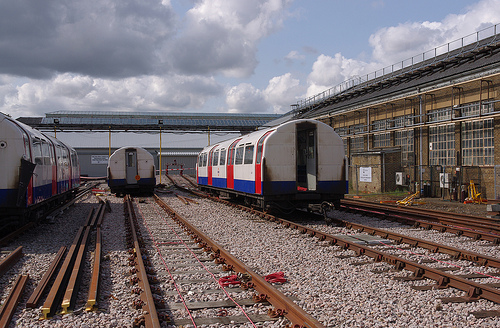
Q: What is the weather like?
A: It is cloudy.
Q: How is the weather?
A: It is cloudy.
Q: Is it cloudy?
A: Yes, it is cloudy.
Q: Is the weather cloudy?
A: Yes, it is cloudy.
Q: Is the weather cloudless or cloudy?
A: It is cloudy.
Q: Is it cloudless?
A: No, it is cloudy.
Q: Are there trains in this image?
A: Yes, there is a train.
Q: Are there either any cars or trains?
A: Yes, there is a train.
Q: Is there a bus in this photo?
A: No, there are no buses.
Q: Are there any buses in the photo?
A: No, there are no buses.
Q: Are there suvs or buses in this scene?
A: No, there are no buses or suvs.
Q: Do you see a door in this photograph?
A: Yes, there is a door.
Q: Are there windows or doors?
A: Yes, there is a door.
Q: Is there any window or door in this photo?
A: Yes, there is a door.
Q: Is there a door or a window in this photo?
A: Yes, there is a door.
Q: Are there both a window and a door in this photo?
A: Yes, there are both a door and a window.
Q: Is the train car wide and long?
A: Yes, the train car is wide and long.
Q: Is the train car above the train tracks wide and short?
A: No, the train car is wide but long.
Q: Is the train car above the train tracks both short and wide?
A: No, the train car is wide but long.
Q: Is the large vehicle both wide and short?
A: No, the train car is wide but long.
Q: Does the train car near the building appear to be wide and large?
A: Yes, the train car is wide and large.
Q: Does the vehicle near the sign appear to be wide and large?
A: Yes, the train car is wide and large.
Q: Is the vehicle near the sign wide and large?
A: Yes, the train car is wide and large.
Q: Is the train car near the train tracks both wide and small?
A: No, the train car is wide but large.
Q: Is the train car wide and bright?
A: Yes, the train car is wide and bright.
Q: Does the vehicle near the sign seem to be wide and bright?
A: Yes, the train car is wide and bright.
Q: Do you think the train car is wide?
A: Yes, the train car is wide.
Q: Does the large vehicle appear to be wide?
A: Yes, the train car is wide.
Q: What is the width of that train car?
A: The train car is wide.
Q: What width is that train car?
A: The train car is wide.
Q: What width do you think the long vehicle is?
A: The train car is wide.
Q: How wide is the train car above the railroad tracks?
A: The train car is wide.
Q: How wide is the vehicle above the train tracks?
A: The train car is wide.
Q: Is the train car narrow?
A: No, the train car is wide.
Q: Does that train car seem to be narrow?
A: No, the train car is wide.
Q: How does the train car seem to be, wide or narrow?
A: The train car is wide.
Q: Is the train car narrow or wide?
A: The train car is wide.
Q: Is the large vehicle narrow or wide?
A: The train car is wide.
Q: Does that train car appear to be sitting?
A: Yes, the train car is sitting.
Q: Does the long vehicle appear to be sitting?
A: Yes, the train car is sitting.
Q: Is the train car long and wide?
A: Yes, the train car is long and wide.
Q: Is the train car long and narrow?
A: No, the train car is long but wide.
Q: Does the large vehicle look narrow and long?
A: No, the train car is long but wide.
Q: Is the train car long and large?
A: Yes, the train car is long and large.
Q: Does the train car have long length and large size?
A: Yes, the train car is long and large.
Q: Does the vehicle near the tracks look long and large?
A: Yes, the train car is long and large.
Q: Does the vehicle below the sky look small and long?
A: No, the train car is long but large.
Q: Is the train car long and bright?
A: Yes, the train car is long and bright.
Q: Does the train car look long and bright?
A: Yes, the train car is long and bright.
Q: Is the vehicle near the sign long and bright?
A: Yes, the train car is long and bright.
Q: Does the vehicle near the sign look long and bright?
A: Yes, the train car is long and bright.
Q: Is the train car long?
A: Yes, the train car is long.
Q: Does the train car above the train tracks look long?
A: Yes, the train car is long.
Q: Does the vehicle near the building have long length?
A: Yes, the train car is long.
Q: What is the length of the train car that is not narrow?
A: The train car is long.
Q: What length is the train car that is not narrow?
A: The train car is long.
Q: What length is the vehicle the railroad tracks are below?
A: The train car is long.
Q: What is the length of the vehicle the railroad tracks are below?
A: The train car is long.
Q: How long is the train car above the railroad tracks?
A: The train car is long.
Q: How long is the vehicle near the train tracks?
A: The train car is long.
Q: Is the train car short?
A: No, the train car is long.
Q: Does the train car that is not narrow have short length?
A: No, the train car is long.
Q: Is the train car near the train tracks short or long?
A: The train car is long.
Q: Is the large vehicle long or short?
A: The train car is long.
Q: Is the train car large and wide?
A: Yes, the train car is large and wide.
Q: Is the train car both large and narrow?
A: No, the train car is large but wide.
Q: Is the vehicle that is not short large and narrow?
A: No, the train car is large but wide.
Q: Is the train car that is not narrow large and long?
A: Yes, the train car is large and long.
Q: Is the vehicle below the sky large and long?
A: Yes, the train car is large and long.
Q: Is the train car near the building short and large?
A: No, the train car is large but long.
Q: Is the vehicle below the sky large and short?
A: No, the train car is large but long.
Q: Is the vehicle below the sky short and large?
A: No, the train car is large but long.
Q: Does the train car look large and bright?
A: Yes, the train car is large and bright.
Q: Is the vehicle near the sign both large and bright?
A: Yes, the train car is large and bright.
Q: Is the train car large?
A: Yes, the train car is large.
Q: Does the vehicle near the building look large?
A: Yes, the train car is large.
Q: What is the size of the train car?
A: The train car is large.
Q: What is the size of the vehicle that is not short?
A: The train car is large.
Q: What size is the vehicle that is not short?
A: The train car is large.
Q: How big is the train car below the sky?
A: The train car is large.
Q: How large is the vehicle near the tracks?
A: The train car is large.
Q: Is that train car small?
A: No, the train car is large.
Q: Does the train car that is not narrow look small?
A: No, the train car is large.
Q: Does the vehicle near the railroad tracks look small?
A: No, the train car is large.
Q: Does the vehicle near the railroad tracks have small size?
A: No, the train car is large.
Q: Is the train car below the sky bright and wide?
A: Yes, the train car is bright and wide.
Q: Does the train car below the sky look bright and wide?
A: Yes, the train car is bright and wide.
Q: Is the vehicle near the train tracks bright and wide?
A: Yes, the train car is bright and wide.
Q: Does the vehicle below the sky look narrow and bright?
A: No, the train car is bright but wide.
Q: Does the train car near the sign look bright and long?
A: Yes, the train car is bright and long.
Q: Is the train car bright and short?
A: No, the train car is bright but long.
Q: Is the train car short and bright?
A: No, the train car is bright but long.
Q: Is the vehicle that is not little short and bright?
A: No, the train car is bright but long.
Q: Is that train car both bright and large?
A: Yes, the train car is bright and large.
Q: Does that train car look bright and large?
A: Yes, the train car is bright and large.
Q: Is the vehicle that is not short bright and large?
A: Yes, the train car is bright and large.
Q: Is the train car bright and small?
A: No, the train car is bright but large.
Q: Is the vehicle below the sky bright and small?
A: No, the train car is bright but large.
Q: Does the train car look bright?
A: Yes, the train car is bright.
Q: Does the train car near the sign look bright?
A: Yes, the train car is bright.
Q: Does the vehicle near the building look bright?
A: Yes, the train car is bright.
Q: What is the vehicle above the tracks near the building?
A: The vehicle is a train car.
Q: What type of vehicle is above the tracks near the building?
A: The vehicle is a train car.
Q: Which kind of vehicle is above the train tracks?
A: The vehicle is a train car.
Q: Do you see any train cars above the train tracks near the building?
A: Yes, there is a train car above the train tracks.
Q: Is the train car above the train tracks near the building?
A: Yes, the train car is above the train tracks.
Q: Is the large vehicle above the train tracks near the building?
A: Yes, the train car is above the train tracks.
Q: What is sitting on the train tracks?
A: The train car is sitting on the train tracks.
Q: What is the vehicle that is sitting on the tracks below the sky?
A: The vehicle is a train car.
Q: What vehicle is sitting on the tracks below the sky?
A: The vehicle is a train car.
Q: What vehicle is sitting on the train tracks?
A: The vehicle is a train car.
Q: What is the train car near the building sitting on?
A: The train car is sitting on the train tracks.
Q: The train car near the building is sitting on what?
A: The train car is sitting on the train tracks.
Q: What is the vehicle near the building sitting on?
A: The train car is sitting on the train tracks.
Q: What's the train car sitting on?
A: The train car is sitting on the train tracks.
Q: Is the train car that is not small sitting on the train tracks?
A: Yes, the train car is sitting on the train tracks.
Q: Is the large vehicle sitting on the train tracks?
A: Yes, the train car is sitting on the train tracks.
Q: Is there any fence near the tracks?
A: No, there is a train car near the tracks.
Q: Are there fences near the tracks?
A: No, there is a train car near the tracks.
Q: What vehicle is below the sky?
A: The vehicle is a train car.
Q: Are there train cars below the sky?
A: Yes, there is a train car below the sky.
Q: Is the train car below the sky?
A: Yes, the train car is below the sky.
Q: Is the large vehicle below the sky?
A: Yes, the train car is below the sky.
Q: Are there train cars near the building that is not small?
A: Yes, there is a train car near the building.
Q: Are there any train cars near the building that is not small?
A: Yes, there is a train car near the building.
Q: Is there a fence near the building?
A: No, there is a train car near the building.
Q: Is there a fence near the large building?
A: No, there is a train car near the building.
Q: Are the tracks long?
A: Yes, the tracks are long.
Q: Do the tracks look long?
A: Yes, the tracks are long.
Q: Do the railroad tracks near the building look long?
A: Yes, the tracks are long.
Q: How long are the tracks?
A: The tracks are long.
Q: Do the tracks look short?
A: No, the tracks are long.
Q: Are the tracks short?
A: No, the tracks are long.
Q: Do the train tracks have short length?
A: No, the train tracks are long.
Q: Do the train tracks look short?
A: No, the train tracks are long.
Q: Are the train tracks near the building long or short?
A: The tracks are long.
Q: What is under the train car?
A: The tracks are under the train car.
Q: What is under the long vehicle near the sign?
A: The tracks are under the train car.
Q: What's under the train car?
A: The tracks are under the train car.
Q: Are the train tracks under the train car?
A: Yes, the train tracks are under the train car.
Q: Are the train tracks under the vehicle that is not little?
A: Yes, the train tracks are under the train car.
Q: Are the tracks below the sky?
A: Yes, the tracks are below the sky.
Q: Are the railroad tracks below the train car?
A: Yes, the railroad tracks are below the train car.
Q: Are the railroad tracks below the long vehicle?
A: Yes, the railroad tracks are below the train car.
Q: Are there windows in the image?
A: Yes, there are windows.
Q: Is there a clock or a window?
A: Yes, there are windows.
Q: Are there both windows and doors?
A: Yes, there are both windows and a door.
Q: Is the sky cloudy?
A: Yes, the sky is cloudy.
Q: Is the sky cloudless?
A: No, the sky is cloudy.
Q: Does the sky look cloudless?
A: No, the sky is cloudy.